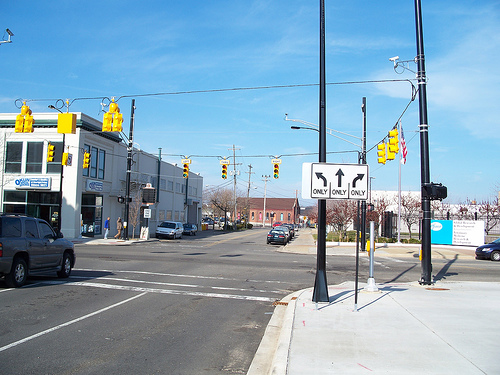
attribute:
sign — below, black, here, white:
[300, 158, 380, 207]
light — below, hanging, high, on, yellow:
[171, 151, 201, 187]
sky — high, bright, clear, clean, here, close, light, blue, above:
[138, 17, 273, 77]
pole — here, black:
[292, 205, 373, 297]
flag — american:
[390, 123, 418, 168]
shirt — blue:
[102, 218, 112, 233]